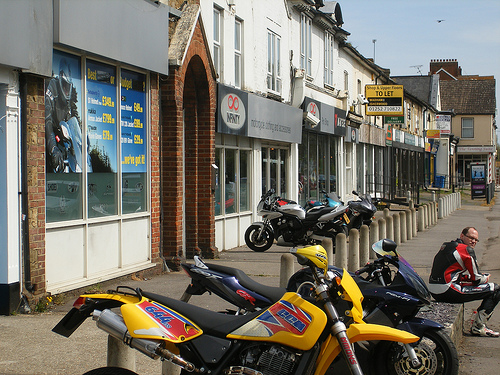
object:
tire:
[385, 316, 459, 375]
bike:
[52, 245, 421, 375]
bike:
[245, 189, 352, 253]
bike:
[178, 234, 462, 374]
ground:
[391, 143, 429, 192]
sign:
[219, 91, 246, 129]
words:
[367, 85, 403, 112]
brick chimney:
[428, 58, 461, 79]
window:
[459, 116, 473, 138]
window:
[211, 4, 231, 84]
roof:
[389, 59, 493, 117]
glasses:
[463, 234, 480, 242]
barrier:
[280, 254, 294, 293]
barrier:
[321, 238, 334, 266]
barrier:
[348, 229, 360, 272]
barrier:
[369, 221, 379, 260]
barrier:
[399, 211, 406, 244]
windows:
[233, 17, 241, 91]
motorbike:
[307, 190, 379, 224]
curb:
[406, 301, 467, 353]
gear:
[428, 227, 500, 338]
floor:
[0, 187, 500, 375]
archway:
[162, 5, 219, 270]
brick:
[148, 0, 220, 261]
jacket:
[426, 240, 489, 293]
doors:
[44, 46, 151, 294]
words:
[121, 94, 150, 168]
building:
[0, 0, 500, 316]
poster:
[43, 48, 146, 174]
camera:
[351, 94, 369, 105]